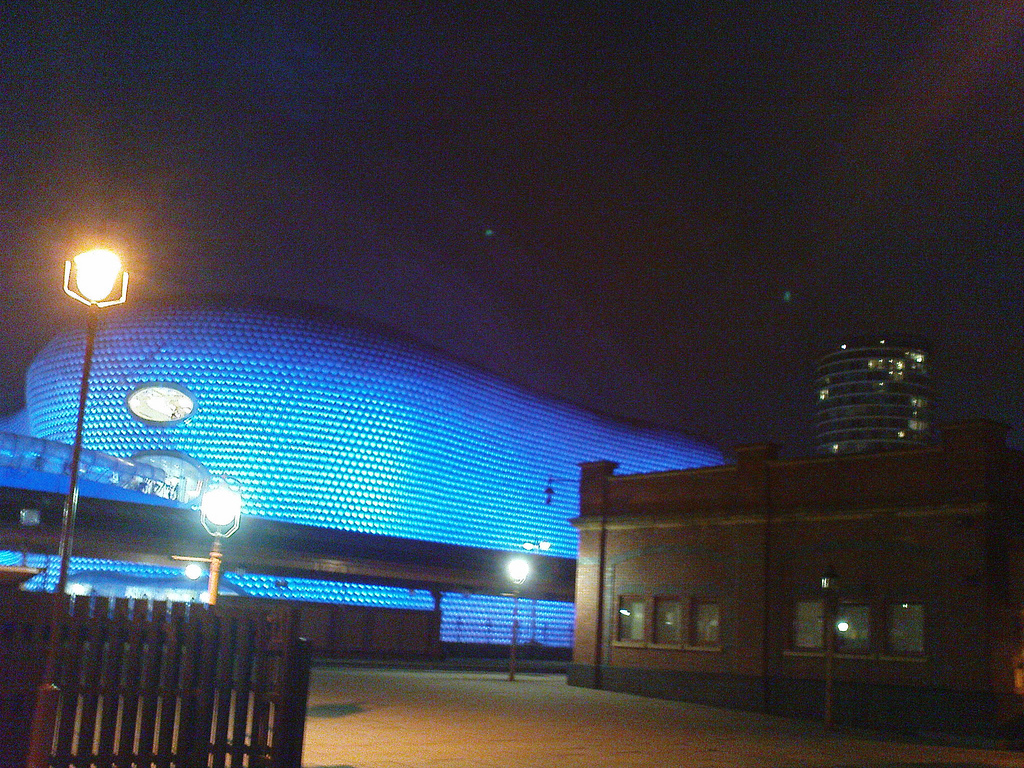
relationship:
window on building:
[687, 592, 726, 653] [566, 417, 1022, 748]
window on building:
[789, 595, 826, 658] [566, 417, 1022, 748]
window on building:
[611, 590, 653, 649] [568, 420, 992, 717]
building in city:
[810, 331, 949, 457] [633, 238, 971, 444]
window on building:
[792, 595, 838, 662] [568, 420, 992, 717]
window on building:
[618, 597, 646, 643] [564, 431, 992, 700]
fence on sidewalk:
[4, 575, 318, 761] [341, 668, 616, 749]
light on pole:
[51, 230, 142, 304] [39, 316, 115, 593]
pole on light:
[43, 314, 111, 595] [49, 223, 140, 319]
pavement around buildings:
[345, 687, 642, 765] [544, 409, 992, 680]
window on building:
[652, 597, 694, 660] [568, 420, 992, 717]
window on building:
[791, 599, 826, 651] [566, 417, 1022, 748]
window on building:
[835, 598, 872, 657] [566, 417, 1022, 748]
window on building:
[887, 598, 929, 665] [566, 417, 1022, 748]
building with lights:
[807, 332, 939, 462] [865, 350, 941, 433]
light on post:
[199, 486, 245, 528] [212, 534, 225, 601]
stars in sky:
[483, 218, 793, 301] [7, 2, 1012, 450]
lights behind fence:
[63, 231, 249, 534] [4, 575, 318, 761]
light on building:
[128, 378, 198, 422] [1, 287, 738, 638]